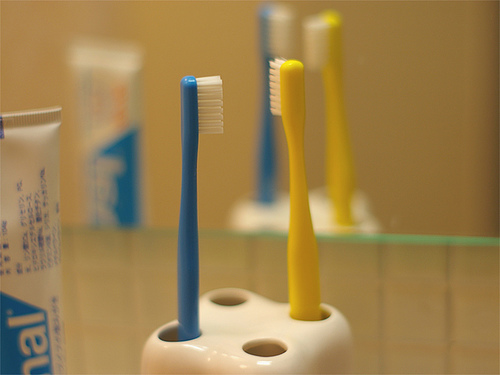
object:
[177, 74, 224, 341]
toothbrush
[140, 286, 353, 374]
holder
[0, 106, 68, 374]
toothpaste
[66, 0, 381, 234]
reflection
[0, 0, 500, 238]
mirror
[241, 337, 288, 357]
hole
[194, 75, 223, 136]
bristles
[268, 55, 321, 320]
toothbrush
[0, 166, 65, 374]
foreign letters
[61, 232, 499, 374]
wall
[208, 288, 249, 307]
hole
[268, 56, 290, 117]
bristles